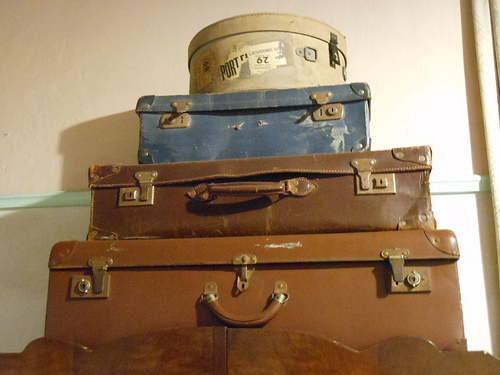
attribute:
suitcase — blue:
[134, 84, 390, 160]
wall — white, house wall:
[4, 3, 141, 165]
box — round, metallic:
[182, 8, 352, 99]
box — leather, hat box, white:
[185, 11, 347, 96]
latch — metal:
[309, 88, 345, 120]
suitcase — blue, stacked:
[104, 72, 394, 167]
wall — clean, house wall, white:
[3, 4, 498, 360]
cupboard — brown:
[30, 230, 471, 367]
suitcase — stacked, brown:
[60, 126, 385, 271]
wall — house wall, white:
[388, 35, 445, 122]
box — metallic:
[34, 223, 481, 347]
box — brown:
[49, 231, 473, 351]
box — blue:
[133, 77, 373, 165]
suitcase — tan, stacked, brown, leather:
[37, 228, 472, 352]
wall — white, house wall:
[18, 17, 109, 160]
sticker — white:
[213, 44, 290, 84]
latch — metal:
[343, 151, 379, 194]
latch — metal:
[224, 241, 261, 304]